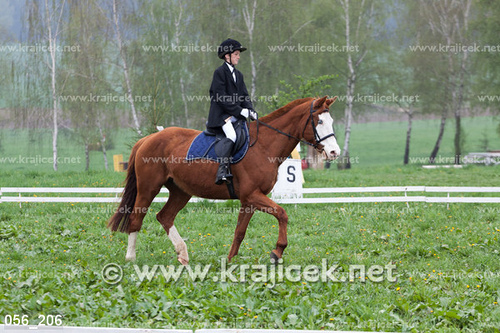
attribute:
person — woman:
[205, 37, 257, 185]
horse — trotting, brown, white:
[108, 96, 343, 267]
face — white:
[314, 110, 341, 161]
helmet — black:
[216, 36, 246, 60]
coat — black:
[206, 60, 253, 134]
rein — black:
[246, 110, 317, 149]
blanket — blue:
[186, 121, 250, 162]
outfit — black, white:
[208, 37, 265, 140]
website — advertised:
[103, 259, 409, 291]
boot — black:
[214, 137, 237, 185]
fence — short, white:
[2, 185, 499, 208]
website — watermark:
[270, 41, 362, 59]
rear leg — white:
[156, 192, 195, 264]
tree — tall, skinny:
[341, 4, 371, 171]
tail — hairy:
[110, 136, 147, 235]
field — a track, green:
[0, 203, 498, 331]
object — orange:
[111, 153, 125, 174]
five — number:
[13, 313, 22, 325]